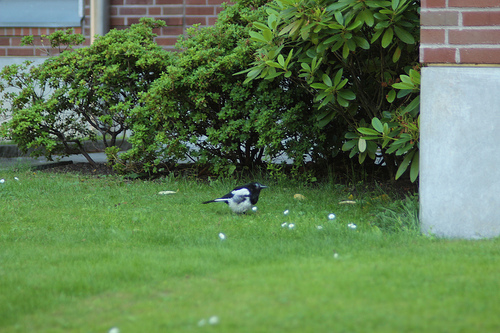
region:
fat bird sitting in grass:
[200, 175, 279, 220]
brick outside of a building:
[425, 3, 498, 56]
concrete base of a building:
[427, 76, 496, 228]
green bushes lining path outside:
[2, 13, 413, 177]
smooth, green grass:
[293, 260, 488, 323]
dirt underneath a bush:
[65, 149, 109, 172]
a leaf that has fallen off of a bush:
[340, 195, 359, 205]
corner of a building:
[422, 2, 499, 232]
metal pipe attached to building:
[87, 1, 110, 51]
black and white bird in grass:
[200, 176, 272, 216]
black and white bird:
[207, 179, 267, 219]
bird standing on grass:
[191, 158, 280, 243]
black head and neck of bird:
[248, 183, 259, 203]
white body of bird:
[229, 187, 251, 214]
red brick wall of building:
[5, 2, 492, 61]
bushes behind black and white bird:
[14, 7, 414, 174]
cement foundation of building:
[0, 56, 499, 227]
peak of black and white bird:
[257, 184, 270, 194]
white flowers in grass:
[92, 204, 361, 332]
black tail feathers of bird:
[200, 195, 222, 214]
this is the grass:
[41, 178, 123, 232]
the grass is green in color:
[40, 207, 156, 288]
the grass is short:
[15, 184, 152, 294]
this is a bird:
[192, 174, 268, 213]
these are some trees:
[7, 0, 419, 169]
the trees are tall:
[183, 27, 411, 162]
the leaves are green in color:
[273, 22, 370, 76]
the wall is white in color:
[422, 80, 496, 162]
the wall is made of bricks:
[428, 0, 498, 57]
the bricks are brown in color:
[451, 4, 498, 44]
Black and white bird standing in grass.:
[214, 173, 266, 250]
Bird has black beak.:
[256, 175, 268, 193]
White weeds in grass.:
[276, 202, 383, 257]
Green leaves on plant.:
[354, 128, 362, 154]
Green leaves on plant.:
[394, 71, 410, 95]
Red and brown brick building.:
[438, 17, 493, 65]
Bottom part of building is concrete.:
[419, 71, 466, 204]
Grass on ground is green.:
[26, 188, 223, 291]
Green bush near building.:
[28, 57, 151, 130]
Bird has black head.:
[246, 173, 266, 203]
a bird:
[201, 176, 268, 219]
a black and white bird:
[201, 181, 270, 216]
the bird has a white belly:
[206, 180, 268, 213]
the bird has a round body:
[202, 180, 272, 215]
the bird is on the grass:
[193, 173, 351, 254]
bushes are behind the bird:
[3, 3, 423, 202]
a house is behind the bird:
[2, 3, 499, 256]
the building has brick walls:
[0, 2, 499, 127]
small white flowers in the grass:
[4, 175, 393, 327]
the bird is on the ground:
[194, 173, 276, 221]